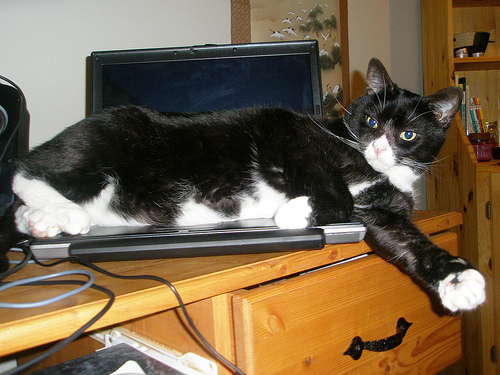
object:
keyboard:
[14, 334, 213, 373]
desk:
[0, 210, 464, 374]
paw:
[439, 266, 493, 318]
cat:
[12, 57, 489, 315]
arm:
[358, 189, 481, 291]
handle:
[343, 314, 415, 362]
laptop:
[31, 39, 357, 267]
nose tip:
[373, 143, 387, 158]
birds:
[251, 0, 345, 96]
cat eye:
[363, 114, 380, 130]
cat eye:
[398, 128, 417, 143]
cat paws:
[20, 213, 60, 243]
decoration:
[227, 2, 349, 113]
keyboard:
[31, 224, 366, 261]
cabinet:
[421, 1, 500, 375]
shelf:
[452, 54, 497, 64]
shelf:
[417, 1, 496, 371]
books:
[454, 74, 486, 140]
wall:
[1, 4, 433, 210]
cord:
[0, 248, 250, 373]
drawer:
[216, 231, 465, 374]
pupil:
[394, 127, 420, 146]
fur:
[64, 132, 117, 190]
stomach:
[119, 169, 283, 227]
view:
[3, 0, 498, 318]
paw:
[273, 192, 312, 230]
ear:
[362, 56, 397, 98]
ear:
[423, 85, 466, 129]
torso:
[12, 100, 335, 232]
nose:
[370, 133, 390, 156]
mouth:
[360, 151, 395, 168]